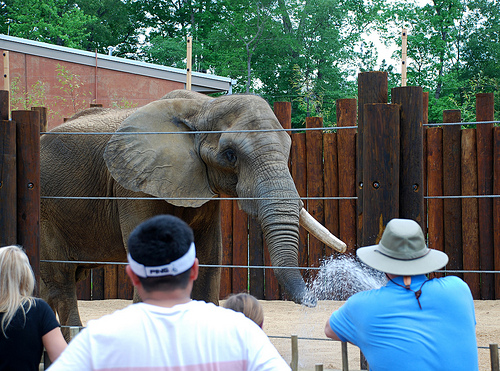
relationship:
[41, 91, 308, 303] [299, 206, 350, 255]
elephant has a tusk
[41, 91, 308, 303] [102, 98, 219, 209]
elephant has an ear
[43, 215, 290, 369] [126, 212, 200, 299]
man has a head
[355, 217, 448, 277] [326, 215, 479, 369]
hat on man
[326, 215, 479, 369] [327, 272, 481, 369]
man wearing a t-shirt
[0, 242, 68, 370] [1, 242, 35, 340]
woman has hair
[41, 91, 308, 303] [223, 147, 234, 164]
elephant has an eye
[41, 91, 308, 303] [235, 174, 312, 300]
elephant has a trunk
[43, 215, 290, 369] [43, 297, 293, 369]
man wearing a shirt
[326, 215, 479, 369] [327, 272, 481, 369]
man wearing shirt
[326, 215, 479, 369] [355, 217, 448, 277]
man wearing hat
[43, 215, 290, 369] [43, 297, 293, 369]
man wearing shirt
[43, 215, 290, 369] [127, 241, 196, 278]
man wearing a head band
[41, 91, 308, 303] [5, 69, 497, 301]
elephant inside of a fence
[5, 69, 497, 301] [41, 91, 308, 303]
fence behind elephant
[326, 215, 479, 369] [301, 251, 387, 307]
man spraying water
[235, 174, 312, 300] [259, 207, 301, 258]
trunk has ridges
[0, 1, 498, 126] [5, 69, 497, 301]
trees are behind fence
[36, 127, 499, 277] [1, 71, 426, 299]
wire attached to posts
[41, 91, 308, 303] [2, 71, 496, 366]
elephant in a pen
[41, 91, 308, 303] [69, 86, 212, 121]
elephant has a hump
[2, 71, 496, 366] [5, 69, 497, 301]
pen made of fence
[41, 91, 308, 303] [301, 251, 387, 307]
elephant spraying water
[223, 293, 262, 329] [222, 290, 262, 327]
kid has hair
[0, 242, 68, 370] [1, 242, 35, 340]
woman has blonde hair